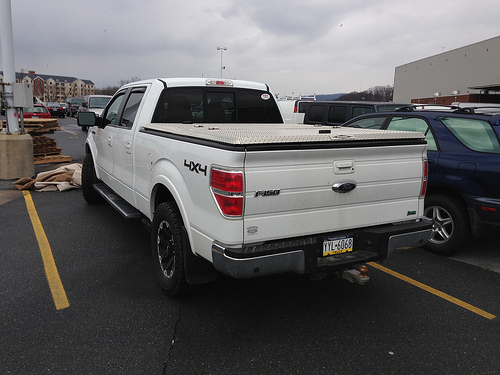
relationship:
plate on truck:
[321, 235, 352, 257] [76, 75, 435, 298]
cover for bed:
[141, 120, 426, 148] [131, 127, 432, 249]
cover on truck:
[141, 120, 426, 148] [76, 75, 435, 298]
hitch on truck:
[339, 265, 370, 286] [76, 75, 435, 298]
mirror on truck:
[75, 109, 96, 128] [76, 75, 435, 298]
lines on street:
[20, 186, 68, 312] [1, 115, 499, 374]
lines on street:
[59, 125, 77, 137] [1, 115, 499, 374]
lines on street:
[364, 257, 497, 321] [1, 115, 499, 374]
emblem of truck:
[332, 180, 359, 194] [76, 75, 435, 298]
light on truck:
[205, 78, 234, 90] [76, 75, 435, 298]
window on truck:
[149, 84, 287, 126] [76, 75, 435, 298]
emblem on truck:
[332, 180, 359, 194] [76, 75, 435, 298]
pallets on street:
[2, 116, 63, 138] [1, 115, 499, 374]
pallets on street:
[28, 134, 74, 166] [1, 115, 499, 374]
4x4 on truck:
[181, 157, 209, 177] [76, 75, 435, 298]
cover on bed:
[141, 120, 426, 148] [131, 127, 432, 249]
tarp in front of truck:
[13, 160, 83, 194] [76, 75, 435, 298]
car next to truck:
[322, 110, 500, 257] [76, 75, 435, 298]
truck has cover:
[76, 75, 435, 298] [141, 120, 426, 148]